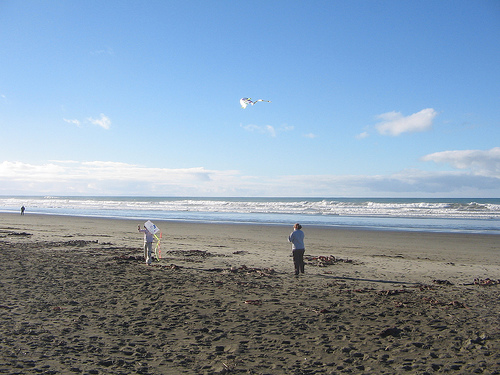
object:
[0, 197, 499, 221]
wave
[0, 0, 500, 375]
photo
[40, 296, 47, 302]
tracks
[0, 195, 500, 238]
water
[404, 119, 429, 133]
clouds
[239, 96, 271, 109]
kite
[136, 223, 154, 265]
person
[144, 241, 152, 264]
pants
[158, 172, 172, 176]
clouds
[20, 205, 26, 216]
person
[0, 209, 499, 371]
beach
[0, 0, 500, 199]
sky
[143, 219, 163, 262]
kite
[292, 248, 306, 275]
pants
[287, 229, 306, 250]
sweater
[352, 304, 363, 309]
prints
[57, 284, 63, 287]
prints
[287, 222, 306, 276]
people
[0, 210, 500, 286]
edge